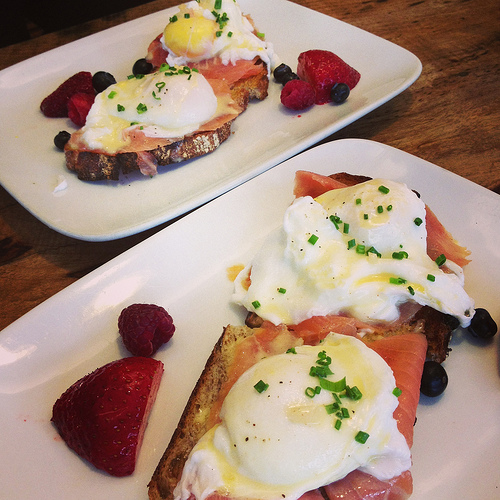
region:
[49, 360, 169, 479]
sliced strawberry on white plate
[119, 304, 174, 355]
raspberry on white plate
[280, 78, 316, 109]
raspberry on white plate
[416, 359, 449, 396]
blueberry on white plate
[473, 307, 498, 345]
blueberry on white plate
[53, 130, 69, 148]
blueberry on white plate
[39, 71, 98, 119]
sliced strawberry on whiteplate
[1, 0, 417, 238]
white plate with food on it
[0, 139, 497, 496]
white plate with food on it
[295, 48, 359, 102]
sliced strawberry on white plate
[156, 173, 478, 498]
A white plate with food on it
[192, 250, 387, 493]
Some type of fish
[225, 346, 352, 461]
Sour creme on the fish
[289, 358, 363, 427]
A green spice on sour creme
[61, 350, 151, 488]
A half of a red strawberry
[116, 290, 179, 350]
A red raspberry on plate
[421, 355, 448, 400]
Blueberries on a white plate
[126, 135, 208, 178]
Brown crust on fish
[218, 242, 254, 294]
A yellow gravy or oil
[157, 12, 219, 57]
Yellow food on sour creme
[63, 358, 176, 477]
a strawberry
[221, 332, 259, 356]
salmon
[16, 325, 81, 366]
a shadow on the plate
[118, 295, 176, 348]
a rasberry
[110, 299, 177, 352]
the rasberry is red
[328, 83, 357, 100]
the blueberry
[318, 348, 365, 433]
the chives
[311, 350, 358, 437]
the chives are green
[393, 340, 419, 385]
the salmon is pink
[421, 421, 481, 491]
a white plate on the table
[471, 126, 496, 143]
part of a table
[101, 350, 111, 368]
side of a plate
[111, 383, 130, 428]
part of a cherry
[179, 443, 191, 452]
side of a plate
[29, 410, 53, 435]
part of a plate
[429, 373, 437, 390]
part of a cherry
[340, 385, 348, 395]
part of a vegetable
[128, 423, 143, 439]
edge of a cherry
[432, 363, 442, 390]
part of a cherry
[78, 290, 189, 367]
Red fruit on white plate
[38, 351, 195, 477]
Red fruit on white plate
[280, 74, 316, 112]
Red fruit on white plate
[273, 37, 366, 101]
Red fruit on white plate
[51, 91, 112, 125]
Red fruit on white plate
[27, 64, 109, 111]
Red fruit on white plate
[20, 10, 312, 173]
Delicious looking food on a plate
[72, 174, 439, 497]
Delicious looking food on a plate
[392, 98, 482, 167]
Dark brown wood grain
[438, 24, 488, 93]
Dark brown wood grain